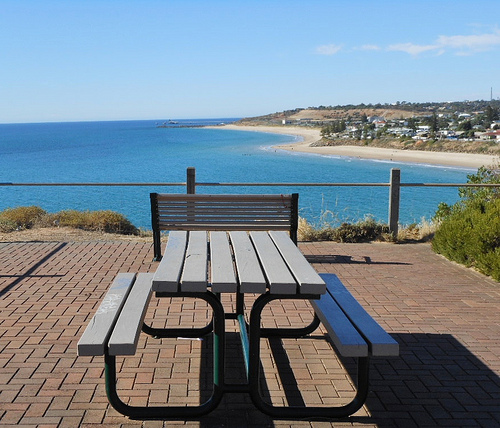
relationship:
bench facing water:
[147, 189, 301, 256] [0, 117, 499, 235]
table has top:
[76, 229, 399, 423] [152, 230, 328, 300]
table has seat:
[76, 229, 399, 423] [74, 272, 153, 356]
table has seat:
[76, 229, 399, 423] [300, 274, 400, 361]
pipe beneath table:
[103, 292, 367, 421] [76, 229, 399, 423]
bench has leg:
[147, 189, 301, 256] [148, 229, 166, 260]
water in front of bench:
[0, 117, 499, 235] [147, 189, 301, 256]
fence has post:
[2, 165, 499, 235] [181, 166, 204, 228]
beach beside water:
[208, 121, 499, 176] [0, 117, 499, 235]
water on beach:
[0, 117, 499, 235] [208, 121, 499, 176]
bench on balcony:
[147, 189, 301, 256] [2, 230, 499, 425]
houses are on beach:
[278, 99, 498, 148] [208, 121, 499, 176]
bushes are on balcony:
[293, 208, 448, 251] [2, 230, 499, 425]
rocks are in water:
[150, 121, 216, 132] [0, 117, 499, 235]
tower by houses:
[483, 84, 498, 109] [278, 99, 498, 148]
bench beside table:
[147, 189, 301, 256] [76, 229, 399, 423]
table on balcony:
[76, 229, 399, 423] [2, 230, 499, 425]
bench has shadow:
[147, 189, 301, 256] [301, 243, 419, 271]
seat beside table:
[74, 272, 153, 356] [76, 229, 399, 423]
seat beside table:
[300, 274, 400, 361] [76, 229, 399, 423]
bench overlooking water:
[147, 189, 301, 256] [0, 117, 499, 235]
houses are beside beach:
[278, 99, 498, 148] [208, 121, 499, 176]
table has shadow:
[76, 229, 399, 423] [330, 307, 499, 427]